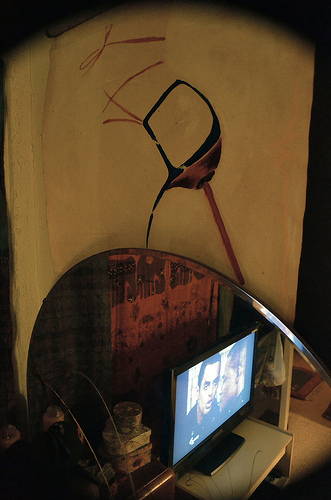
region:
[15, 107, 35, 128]
Peice of a white wall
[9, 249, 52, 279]
Peice of a white wall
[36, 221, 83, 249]
Peice of a white wall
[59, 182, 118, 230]
Peice of a white wall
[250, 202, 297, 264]
Peice of a white wall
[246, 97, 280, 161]
Peice of a white wall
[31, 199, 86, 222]
Peice of a white wall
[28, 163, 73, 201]
Peice of a white wall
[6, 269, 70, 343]
Peice of a white wall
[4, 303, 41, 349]
Peice of a white wall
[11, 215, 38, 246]
Part of a white wall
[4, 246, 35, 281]
Part of a white wall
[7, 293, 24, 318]
Part of a white wall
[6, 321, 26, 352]
Part of a white wall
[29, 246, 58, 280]
Part of a white wall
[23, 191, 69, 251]
Part of a white wall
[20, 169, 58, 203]
Part of a white wall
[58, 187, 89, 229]
Part of a white wall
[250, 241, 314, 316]
Part of a white wall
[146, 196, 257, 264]
Part of a white wall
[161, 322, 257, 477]
A flat screen tv.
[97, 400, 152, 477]
Three boxes on a table.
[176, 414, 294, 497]
A white wood table.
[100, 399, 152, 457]
Two boxes on a table.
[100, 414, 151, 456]
A heart box on a table.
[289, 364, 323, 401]
Part of a welcome mat.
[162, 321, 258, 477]
A tv turned on.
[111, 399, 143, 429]
A round box on a box.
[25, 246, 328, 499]
A round shaped mirror.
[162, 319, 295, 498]
A tv on a table.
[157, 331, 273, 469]
the TV is on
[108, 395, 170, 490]
boxes beside the television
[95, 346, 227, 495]
boxes beside the television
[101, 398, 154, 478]
pile of paper gift boxes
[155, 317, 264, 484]
tv screen is switched on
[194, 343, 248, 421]
two men on a tv screen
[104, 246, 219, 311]
elephants printed on some fabric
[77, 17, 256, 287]
artwork on a wall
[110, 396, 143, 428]
circular shaped gift box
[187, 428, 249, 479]
black tv stand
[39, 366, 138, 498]
two twisted wires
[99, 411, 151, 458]
heart shaped gift box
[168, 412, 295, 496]
white table top